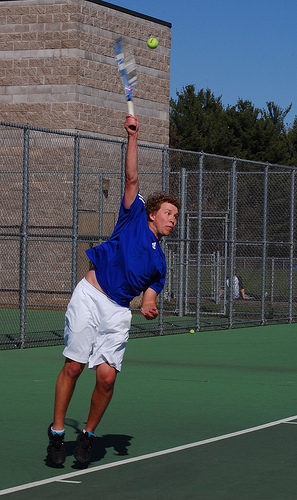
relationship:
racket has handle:
[115, 36, 140, 134] [127, 97, 136, 130]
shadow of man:
[42, 425, 134, 472] [44, 114, 181, 465]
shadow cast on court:
[42, 425, 134, 472] [1, 322, 294, 500]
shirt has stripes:
[86, 186, 167, 308] [137, 190, 146, 206]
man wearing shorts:
[44, 114, 181, 465] [58, 275, 132, 371]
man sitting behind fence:
[217, 268, 271, 301] [0, 120, 296, 351]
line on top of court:
[1, 408, 296, 499] [1, 322, 294, 500]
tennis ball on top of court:
[187, 328, 197, 333] [1, 322, 294, 500]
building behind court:
[0, 1, 170, 309] [0, 302, 294, 500]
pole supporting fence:
[19, 127, 31, 350] [0, 120, 296, 351]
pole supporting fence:
[70, 132, 80, 297] [0, 120, 296, 351]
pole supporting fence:
[195, 150, 205, 333] [0, 120, 296, 351]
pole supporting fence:
[224, 155, 238, 329] [0, 120, 296, 351]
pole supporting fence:
[259, 161, 271, 324] [0, 120, 296, 351]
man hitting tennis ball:
[44, 114, 181, 465] [146, 33, 160, 51]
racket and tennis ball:
[115, 36, 140, 134] [146, 33, 160, 51]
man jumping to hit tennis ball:
[44, 114, 181, 465] [146, 33, 160, 51]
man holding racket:
[44, 114, 181, 465] [115, 36, 140, 134]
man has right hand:
[44, 114, 181, 465] [123, 112, 141, 138]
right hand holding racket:
[123, 112, 141, 138] [115, 36, 140, 134]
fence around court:
[0, 120, 296, 351] [1, 322, 294, 500]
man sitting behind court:
[217, 268, 271, 301] [0, 302, 294, 500]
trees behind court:
[166, 83, 296, 256] [0, 302, 294, 500]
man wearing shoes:
[44, 114, 181, 465] [44, 422, 95, 469]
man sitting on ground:
[217, 268, 271, 301] [170, 260, 296, 313]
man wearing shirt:
[44, 114, 181, 465] [86, 186, 167, 308]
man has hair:
[44, 114, 181, 465] [144, 190, 182, 215]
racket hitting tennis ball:
[115, 36, 140, 134] [146, 33, 160, 51]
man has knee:
[44, 114, 181, 465] [98, 369, 119, 391]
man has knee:
[44, 114, 181, 465] [66, 359, 82, 376]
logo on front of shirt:
[150, 238, 157, 250] [86, 186, 167, 308]